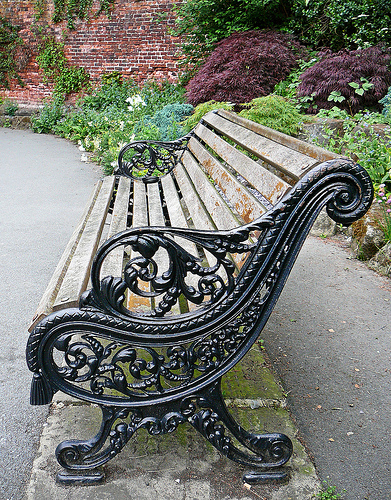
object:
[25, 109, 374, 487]
bench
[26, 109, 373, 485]
edges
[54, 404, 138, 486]
leg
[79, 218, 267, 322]
arm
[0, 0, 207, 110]
wall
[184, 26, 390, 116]
leaves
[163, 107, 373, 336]
backrest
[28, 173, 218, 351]
seat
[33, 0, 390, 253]
bushes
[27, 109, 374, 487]
metal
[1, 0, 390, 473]
garden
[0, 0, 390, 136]
ivy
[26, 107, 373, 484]
design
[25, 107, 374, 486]
curves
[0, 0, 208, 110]
brick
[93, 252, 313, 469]
moss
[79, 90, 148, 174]
flowers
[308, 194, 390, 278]
rocks